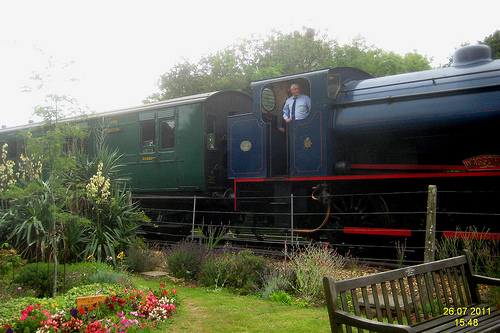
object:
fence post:
[423, 185, 438, 262]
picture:
[0, 0, 500, 333]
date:
[443, 306, 490, 327]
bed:
[0, 261, 180, 333]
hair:
[290, 83, 300, 89]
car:
[0, 89, 253, 192]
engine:
[226, 44, 499, 216]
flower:
[5, 279, 178, 333]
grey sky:
[0, 0, 500, 130]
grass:
[200, 297, 292, 328]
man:
[283, 83, 311, 122]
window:
[161, 117, 175, 148]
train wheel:
[329, 194, 389, 244]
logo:
[463, 155, 499, 171]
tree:
[137, 26, 500, 105]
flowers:
[86, 160, 111, 210]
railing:
[330, 72, 477, 106]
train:
[0, 45, 500, 282]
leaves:
[142, 26, 434, 106]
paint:
[174, 103, 206, 192]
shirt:
[282, 94, 310, 120]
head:
[291, 83, 300, 95]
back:
[322, 249, 500, 333]